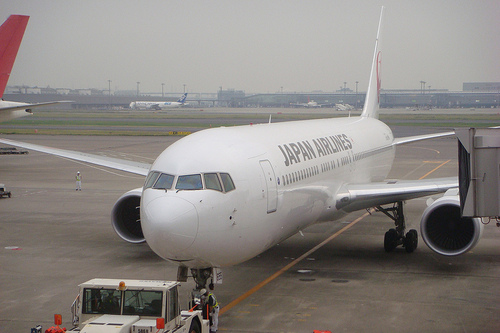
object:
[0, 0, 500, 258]
plane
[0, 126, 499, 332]
tarmack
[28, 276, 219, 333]
car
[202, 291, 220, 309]
vest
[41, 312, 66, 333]
cover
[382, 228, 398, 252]
tire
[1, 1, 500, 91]
sky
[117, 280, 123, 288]
light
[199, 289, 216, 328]
guy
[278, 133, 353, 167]
words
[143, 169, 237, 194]
windshield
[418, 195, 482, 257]
engine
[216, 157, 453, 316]
line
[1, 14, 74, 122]
tail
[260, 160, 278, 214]
door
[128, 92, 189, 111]
plane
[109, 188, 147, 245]
engine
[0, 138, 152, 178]
wing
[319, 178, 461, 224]
wing